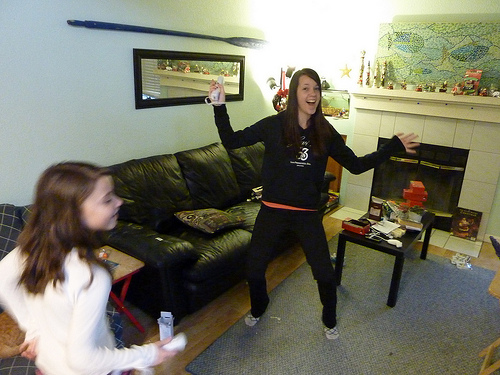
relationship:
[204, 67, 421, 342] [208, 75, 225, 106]
girl holding remote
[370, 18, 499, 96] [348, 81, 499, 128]
picture above mantle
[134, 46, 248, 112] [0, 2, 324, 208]
mirror hanging on wall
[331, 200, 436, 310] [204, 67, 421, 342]
coffee table behind girl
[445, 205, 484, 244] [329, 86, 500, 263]
book near fireplace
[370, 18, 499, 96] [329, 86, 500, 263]
picture above fireplace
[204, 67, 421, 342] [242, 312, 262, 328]
girl wearing sock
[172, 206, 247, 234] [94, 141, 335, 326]
cushion on top of couch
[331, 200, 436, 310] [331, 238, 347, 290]
coffee table has leg